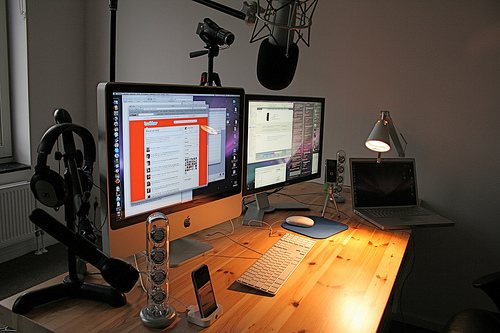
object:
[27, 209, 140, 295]
mic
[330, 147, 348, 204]
speaker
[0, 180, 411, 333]
table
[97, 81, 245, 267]
computer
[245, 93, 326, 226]
computer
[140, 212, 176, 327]
speaker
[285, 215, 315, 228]
mouse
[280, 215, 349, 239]
mouse pad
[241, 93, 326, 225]
computer monitor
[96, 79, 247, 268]
computer monitor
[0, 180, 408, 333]
desk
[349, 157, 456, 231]
macbook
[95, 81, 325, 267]
computer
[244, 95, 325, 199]
monitor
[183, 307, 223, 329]
dock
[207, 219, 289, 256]
wired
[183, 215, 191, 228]
logo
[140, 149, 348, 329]
speakers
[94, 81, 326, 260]
computer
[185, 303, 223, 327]
charging dock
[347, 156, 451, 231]
laptop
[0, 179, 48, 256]
radiator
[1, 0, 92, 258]
wall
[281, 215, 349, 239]
mousepad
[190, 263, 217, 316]
cell phone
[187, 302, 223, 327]
charger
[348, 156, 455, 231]
laptop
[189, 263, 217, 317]
phone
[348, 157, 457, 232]
silver laptop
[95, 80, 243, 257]
monitor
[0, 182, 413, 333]
desk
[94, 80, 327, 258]
monitors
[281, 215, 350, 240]
pad